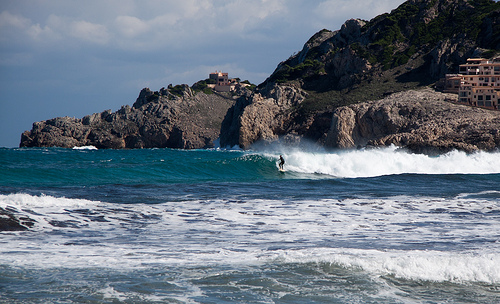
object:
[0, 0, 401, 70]
clouds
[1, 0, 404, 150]
sky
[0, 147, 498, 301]
ocean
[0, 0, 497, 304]
scene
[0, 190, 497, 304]
foam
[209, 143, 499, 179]
foam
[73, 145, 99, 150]
foam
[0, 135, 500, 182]
wave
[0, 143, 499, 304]
rock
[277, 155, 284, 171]
man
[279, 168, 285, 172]
board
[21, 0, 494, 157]
cliff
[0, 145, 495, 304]
water